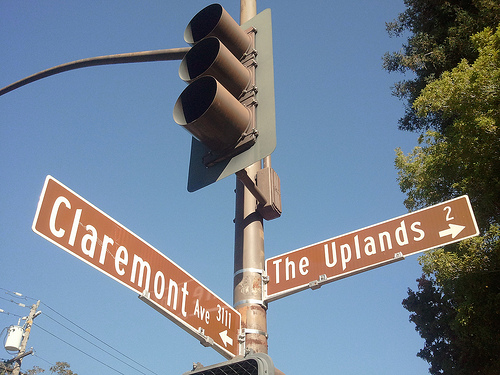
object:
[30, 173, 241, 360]
sign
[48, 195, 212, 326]
claremont ave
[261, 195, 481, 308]
sign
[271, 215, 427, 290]
uplands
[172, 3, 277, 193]
stop light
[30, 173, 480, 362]
intersection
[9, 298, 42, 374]
pole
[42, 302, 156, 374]
wire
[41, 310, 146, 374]
wire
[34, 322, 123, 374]
wire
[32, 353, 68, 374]
wire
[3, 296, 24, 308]
wire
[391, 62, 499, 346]
tree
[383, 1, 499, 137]
tree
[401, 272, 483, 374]
tree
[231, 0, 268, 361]
pole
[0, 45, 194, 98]
street lamp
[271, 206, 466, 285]
lettering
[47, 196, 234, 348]
lettering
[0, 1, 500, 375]
sky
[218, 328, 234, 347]
arrow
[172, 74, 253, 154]
cover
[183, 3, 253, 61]
light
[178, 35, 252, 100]
light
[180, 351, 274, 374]
walking signal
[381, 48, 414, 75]
leaves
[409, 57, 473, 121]
leaves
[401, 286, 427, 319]
leaves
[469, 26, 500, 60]
leaves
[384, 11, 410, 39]
leaves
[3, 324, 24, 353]
box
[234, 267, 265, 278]
fastener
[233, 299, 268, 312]
fastener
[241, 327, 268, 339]
fastener